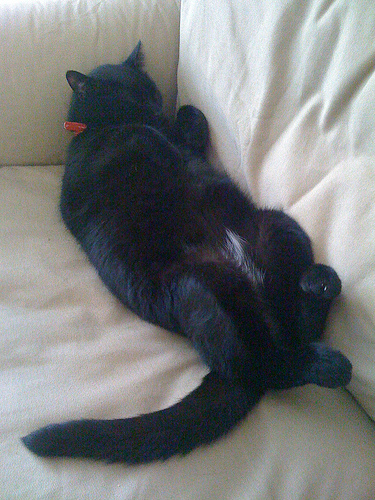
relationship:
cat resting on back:
[20, 40, 356, 465] [74, 180, 172, 323]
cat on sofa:
[20, 40, 356, 465] [1, 6, 369, 498]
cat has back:
[20, 40, 356, 465] [74, 180, 172, 323]